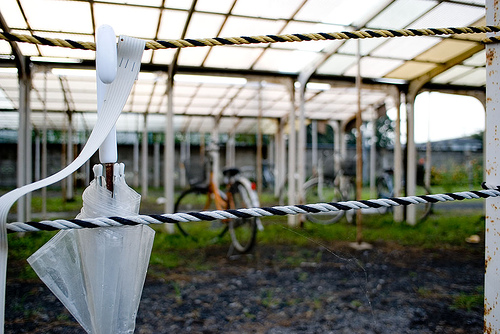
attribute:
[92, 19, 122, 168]
handle — white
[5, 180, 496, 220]
rope — black, white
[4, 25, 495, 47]
rope — weathered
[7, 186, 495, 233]
rope — black, white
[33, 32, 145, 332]
umbrella — clear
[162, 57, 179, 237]
pole — white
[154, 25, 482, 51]
rope — yellow, black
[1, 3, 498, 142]
roof — glass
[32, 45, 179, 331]
umbrella — white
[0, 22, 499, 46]
rope — black, white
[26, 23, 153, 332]
umbrella — white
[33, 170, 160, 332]
umbrella — white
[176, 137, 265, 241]
bike — orange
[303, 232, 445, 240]
grass — green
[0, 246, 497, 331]
dirt —  area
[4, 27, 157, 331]
umbrella — clear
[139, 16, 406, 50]
rope — yellow, black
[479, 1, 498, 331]
pole — white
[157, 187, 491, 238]
grass — green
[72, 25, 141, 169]
handle — white